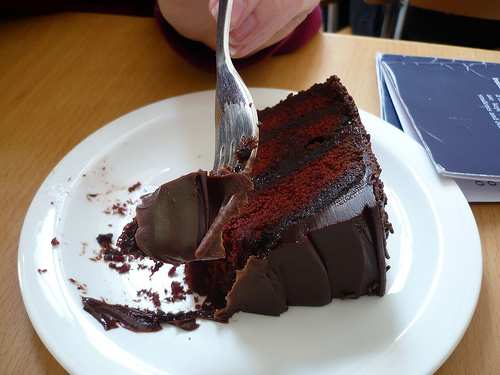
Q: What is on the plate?
A: A piece of cake.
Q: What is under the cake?
A: A plate.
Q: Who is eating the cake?
A: A person.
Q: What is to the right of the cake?
A: A blue book.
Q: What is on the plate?
A: Chocolate cake.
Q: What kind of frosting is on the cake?
A: Chocolate.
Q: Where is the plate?
A: On a table.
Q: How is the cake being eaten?
A: With a fork?.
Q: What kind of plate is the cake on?
A: A white plate.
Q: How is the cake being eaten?
A: With a fork.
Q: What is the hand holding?
A: A fork.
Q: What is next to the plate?
A: A book.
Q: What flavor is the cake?
A: Chocolate.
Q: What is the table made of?
A: Wood.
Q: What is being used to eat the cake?
A: A fork.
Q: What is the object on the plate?
A: A piece of cake.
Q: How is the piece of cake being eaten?
A: Fork.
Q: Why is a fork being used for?
A: Eating cake.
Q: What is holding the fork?
A: Hand.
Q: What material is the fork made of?
A: Metal.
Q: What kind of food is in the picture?
A: A cake.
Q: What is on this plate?
A: Chocolate Cake.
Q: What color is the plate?
A: White.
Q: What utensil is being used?
A: A fork.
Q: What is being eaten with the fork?
A: Chocolate cake.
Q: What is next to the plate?
A: A Booklet.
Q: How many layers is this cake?
A: 2.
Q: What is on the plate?
A: Chocolate Cake.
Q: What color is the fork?
A: Silver.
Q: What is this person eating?
A: Chocolate cake.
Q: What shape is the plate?
A: Round.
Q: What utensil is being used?
A: Fork.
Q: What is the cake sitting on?
A: A plate.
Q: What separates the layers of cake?
A: Frosting.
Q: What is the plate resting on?
A: A table.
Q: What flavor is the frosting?
A: Chocolate.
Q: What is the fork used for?
A: To eat the cake.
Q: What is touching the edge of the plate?
A: A booklet.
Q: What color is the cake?
A: Brown.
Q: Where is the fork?
A: In the cake.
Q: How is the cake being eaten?
A: With a fork.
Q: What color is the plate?
A: White.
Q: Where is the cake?
A: On the plate.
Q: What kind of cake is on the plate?
A: Chocolate.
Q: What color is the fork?
A: Silver.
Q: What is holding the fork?
A: A hand.